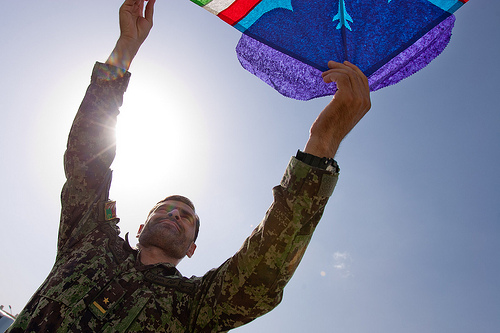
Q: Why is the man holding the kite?
A: To fly.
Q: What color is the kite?
A: Blue.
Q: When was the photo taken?
A: Daytime.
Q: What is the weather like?
A: Sunny.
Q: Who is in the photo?
A: A man.